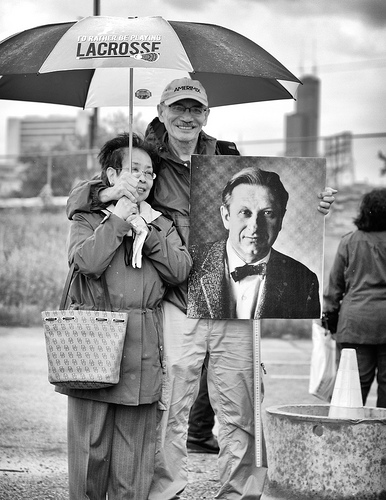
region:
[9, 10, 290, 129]
black and white umbrella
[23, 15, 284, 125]
umbrella is wet from rain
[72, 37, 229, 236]
woman and man holding umbrella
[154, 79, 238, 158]
man smiling wears glasses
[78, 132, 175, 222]
woman has glasses on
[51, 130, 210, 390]
woman has purse on her arm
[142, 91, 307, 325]
man holding portrait of man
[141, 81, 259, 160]
man has cap on his head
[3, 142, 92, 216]
fence with tree on one side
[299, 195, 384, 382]
person carrying white bag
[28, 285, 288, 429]
image is in black and white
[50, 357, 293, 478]
image is in black and white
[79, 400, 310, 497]
image is in black and white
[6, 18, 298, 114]
open umbrella in black and white photo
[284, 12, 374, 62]
clouds in black and white photo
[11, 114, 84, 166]
building in black and white photo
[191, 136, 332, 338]
photo of man in suit in black and white photo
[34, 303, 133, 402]
woman carrying handbag in black and white photo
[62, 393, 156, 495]
woman wearing pants in black and white photo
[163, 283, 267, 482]
man wearing pants in black and white photo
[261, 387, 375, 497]
large metal container in black and white photo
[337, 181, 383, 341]
woman standing with back to camera in black and white photo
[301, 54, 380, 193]
building in black and white photo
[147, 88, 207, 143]
this is an old man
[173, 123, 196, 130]
the old man is smiling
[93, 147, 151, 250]
an old woman is beside the man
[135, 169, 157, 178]
the woman is wearing spectacles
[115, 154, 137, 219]
they are holding an umbrella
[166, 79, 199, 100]
the man is wearing a cap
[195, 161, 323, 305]
this is a persons post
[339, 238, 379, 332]
the woman is looking behind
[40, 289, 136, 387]
the woman is carrying a handbag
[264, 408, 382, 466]
the jar is empty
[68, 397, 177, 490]
grey pinstripe pants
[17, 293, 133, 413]
Dooney and Bourke hand bag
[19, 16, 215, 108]
umbrella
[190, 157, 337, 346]
black and white poster of man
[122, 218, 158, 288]
gloves in hand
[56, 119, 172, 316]
Asian woman in jacket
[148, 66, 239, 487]
Asian man wearing hat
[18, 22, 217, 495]
Asian couple standing underneath umbrella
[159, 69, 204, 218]
smiling Asian man wearing jacket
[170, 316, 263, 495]
wrinkled pants